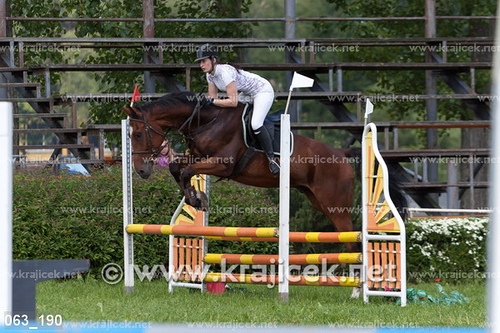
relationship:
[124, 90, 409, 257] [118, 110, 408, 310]
horse jumping over obstacle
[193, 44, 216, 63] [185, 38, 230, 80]
helmet on face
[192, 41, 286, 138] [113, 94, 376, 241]
jockey on horse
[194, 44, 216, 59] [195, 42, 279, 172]
helmet on woman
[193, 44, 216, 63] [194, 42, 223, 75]
helmet on head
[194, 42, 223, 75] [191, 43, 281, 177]
head on woman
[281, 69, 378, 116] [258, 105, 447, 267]
flags on poles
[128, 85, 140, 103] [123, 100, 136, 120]
flag on pole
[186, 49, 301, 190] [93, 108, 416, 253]
woman riding horse